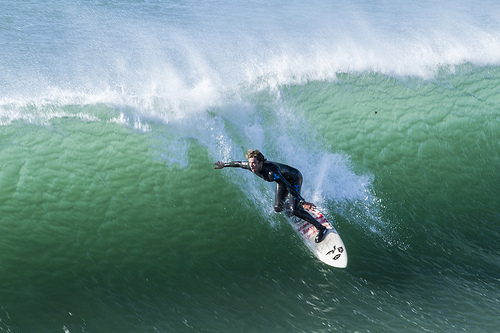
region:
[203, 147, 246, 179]
a surfers hand touching the water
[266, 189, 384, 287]
a red and white surfboard with a man on top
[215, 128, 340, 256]
a man riding a surfboard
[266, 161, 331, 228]
the surfer's black and blue wetsuit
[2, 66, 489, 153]
the crest of the wave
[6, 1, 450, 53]
the white spray from the top of the wave's crest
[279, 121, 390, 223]
the spraying water from the back of the surfboard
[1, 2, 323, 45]
the calm water behind the wave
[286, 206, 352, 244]
the man's front foot on the surfboard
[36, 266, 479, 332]
ocean foam on the water in front of the wave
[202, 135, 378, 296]
man surfing and wearing a wetsuit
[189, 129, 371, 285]
man with blond hair surfing on wave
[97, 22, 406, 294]
surfer riding a wave on a white surfboard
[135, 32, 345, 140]
white sea spray on wave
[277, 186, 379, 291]
white surfboard with red stripes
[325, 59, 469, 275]
multicolored wave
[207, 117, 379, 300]
male surfer riding a large wave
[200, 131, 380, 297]
male surfer wearing a black wetsuit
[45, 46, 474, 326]
large blue wave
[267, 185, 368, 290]
white surfboard on a blue wave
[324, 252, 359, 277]
edge of a swimming board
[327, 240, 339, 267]
surface of a swimming board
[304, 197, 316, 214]
part of the left hand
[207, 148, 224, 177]
part of the right hand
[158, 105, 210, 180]
part of a splash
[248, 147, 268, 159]
hair of a man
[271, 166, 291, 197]
part of a costume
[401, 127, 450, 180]
part of a water body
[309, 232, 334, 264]
surface of a swimming board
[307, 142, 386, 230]
spray of water from surfboard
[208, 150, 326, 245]
man surfing in wetsuit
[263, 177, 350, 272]
surfboard with white, red, and black design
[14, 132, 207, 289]
large cresting ocean wave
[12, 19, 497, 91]
spray from ocean wave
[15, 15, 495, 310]
blue green ocean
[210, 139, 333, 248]
man with curly hair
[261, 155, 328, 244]
black wet suit with blue logo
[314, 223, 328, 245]
water shoes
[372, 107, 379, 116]
ocean debris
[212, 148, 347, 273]
a man in a wetsuit surfing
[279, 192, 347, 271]
a white surfboard with a custom paint job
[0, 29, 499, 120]
white water splash from a wave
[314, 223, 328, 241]
black surfing boots on a surfer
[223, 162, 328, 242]
a black wet suit on a surfer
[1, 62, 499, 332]
the color of the wave is green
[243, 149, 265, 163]
the surfer has blond hair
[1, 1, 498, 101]
the color of the ocean is blue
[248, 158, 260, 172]
the surfers mouth is open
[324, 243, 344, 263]
there are black stickers on the surfboard